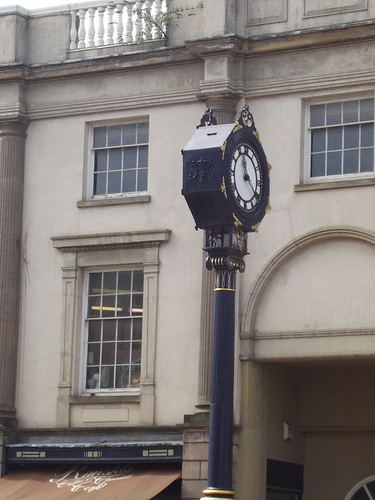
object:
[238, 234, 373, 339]
arch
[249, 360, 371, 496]
entryway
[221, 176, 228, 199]
details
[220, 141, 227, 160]
details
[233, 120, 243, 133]
details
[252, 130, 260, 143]
details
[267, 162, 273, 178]
details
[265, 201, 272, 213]
details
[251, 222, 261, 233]
details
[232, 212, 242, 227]
details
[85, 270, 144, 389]
window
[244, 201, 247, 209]
numerals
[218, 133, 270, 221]
bus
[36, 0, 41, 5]
part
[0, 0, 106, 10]
sky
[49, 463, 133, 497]
writing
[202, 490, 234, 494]
stripes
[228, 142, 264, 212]
clock face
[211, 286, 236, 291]
stripe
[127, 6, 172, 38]
tree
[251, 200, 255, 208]
numerals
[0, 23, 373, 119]
part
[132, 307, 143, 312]
lights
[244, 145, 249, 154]
roman numeral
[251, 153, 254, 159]
roman numeral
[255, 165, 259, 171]
roman numeral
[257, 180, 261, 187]
roman numeral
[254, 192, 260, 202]
roman numeral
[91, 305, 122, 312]
light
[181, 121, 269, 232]
clock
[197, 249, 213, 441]
column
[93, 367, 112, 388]
fan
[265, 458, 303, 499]
door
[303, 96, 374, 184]
window building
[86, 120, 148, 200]
window building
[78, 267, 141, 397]
window building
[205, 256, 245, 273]
gold scrolls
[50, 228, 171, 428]
windowdesign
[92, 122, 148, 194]
small window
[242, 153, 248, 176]
hand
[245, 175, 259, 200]
hand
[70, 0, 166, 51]
decorative railing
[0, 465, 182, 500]
awning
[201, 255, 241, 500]
clock post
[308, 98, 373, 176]
window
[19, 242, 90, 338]
wall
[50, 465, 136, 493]
text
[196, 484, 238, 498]
trimming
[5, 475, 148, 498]
fabric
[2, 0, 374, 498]
building